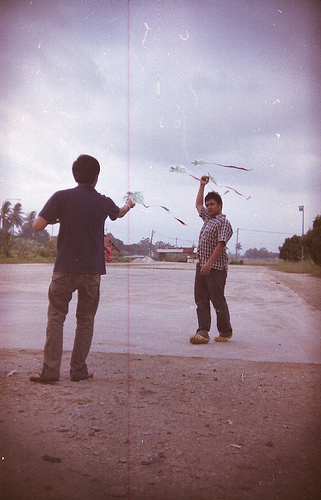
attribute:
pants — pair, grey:
[32, 265, 109, 379]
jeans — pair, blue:
[186, 260, 233, 334]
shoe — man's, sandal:
[24, 363, 64, 386]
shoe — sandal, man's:
[67, 363, 99, 385]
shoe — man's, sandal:
[179, 325, 220, 348]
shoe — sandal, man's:
[213, 324, 239, 345]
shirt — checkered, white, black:
[190, 202, 233, 272]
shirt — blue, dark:
[36, 183, 121, 279]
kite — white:
[116, 184, 150, 216]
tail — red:
[142, 198, 188, 232]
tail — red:
[183, 167, 255, 206]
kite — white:
[161, 158, 195, 179]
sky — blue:
[0, 0, 316, 253]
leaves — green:
[4, 240, 46, 270]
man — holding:
[182, 189, 252, 326]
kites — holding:
[102, 143, 268, 237]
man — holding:
[182, 189, 250, 315]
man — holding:
[149, 172, 258, 312]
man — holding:
[188, 203, 241, 302]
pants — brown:
[36, 266, 129, 393]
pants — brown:
[36, 265, 157, 391]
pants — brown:
[47, 262, 140, 389]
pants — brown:
[32, 259, 116, 372]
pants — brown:
[35, 270, 151, 380]